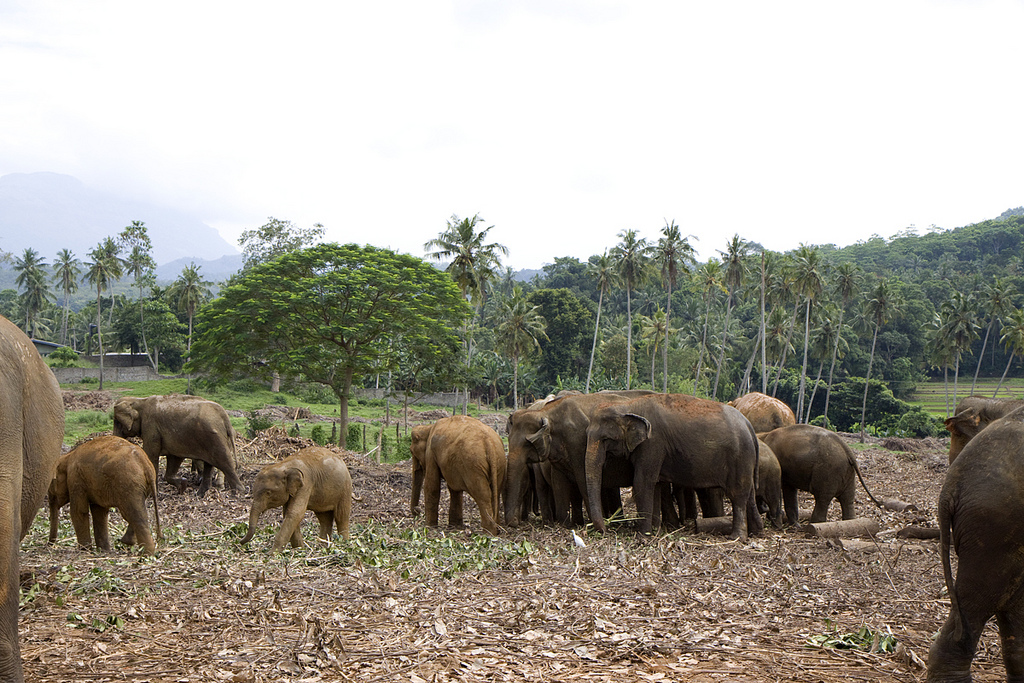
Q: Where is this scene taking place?
A: Wildlife park.